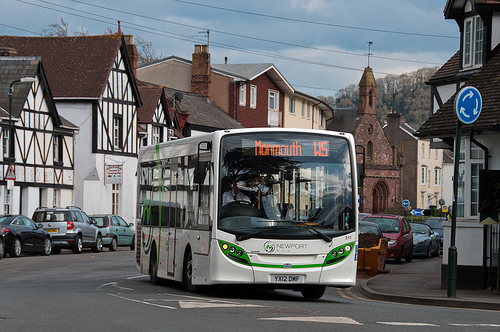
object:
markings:
[179, 301, 264, 309]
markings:
[258, 315, 362, 325]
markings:
[377, 321, 439, 327]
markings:
[449, 321, 500, 325]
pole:
[446, 121, 461, 295]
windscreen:
[221, 134, 352, 233]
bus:
[134, 125, 361, 297]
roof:
[1, 55, 38, 137]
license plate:
[273, 274, 302, 282]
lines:
[251, 263, 323, 268]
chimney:
[123, 32, 138, 77]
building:
[0, 47, 76, 208]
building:
[416, 2, 499, 285]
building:
[333, 68, 403, 214]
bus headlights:
[223, 244, 228, 250]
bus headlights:
[345, 246, 351, 252]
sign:
[104, 163, 123, 183]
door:
[111, 184, 121, 215]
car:
[360, 213, 414, 264]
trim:
[90, 44, 140, 157]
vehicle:
[29, 203, 104, 255]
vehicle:
[87, 211, 136, 249]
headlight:
[388, 240, 398, 247]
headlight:
[222, 243, 229, 250]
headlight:
[343, 245, 352, 252]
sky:
[0, 0, 460, 74]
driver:
[222, 179, 251, 208]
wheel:
[224, 206, 261, 216]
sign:
[452, 87, 481, 125]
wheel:
[180, 251, 193, 293]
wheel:
[13, 237, 24, 257]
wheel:
[42, 238, 52, 255]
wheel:
[73, 237, 83, 254]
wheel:
[95, 236, 103, 252]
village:
[2, 1, 497, 326]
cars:
[1, 213, 52, 258]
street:
[0, 253, 497, 330]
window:
[112, 114, 124, 151]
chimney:
[189, 42, 210, 98]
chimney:
[386, 113, 402, 127]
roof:
[0, 34, 122, 103]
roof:
[131, 84, 163, 125]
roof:
[165, 90, 245, 129]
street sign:
[452, 86, 481, 122]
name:
[276, 243, 306, 250]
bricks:
[208, 83, 211, 89]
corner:
[360, 270, 444, 303]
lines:
[475, 99, 478, 110]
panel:
[320, 243, 357, 285]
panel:
[210, 238, 253, 283]